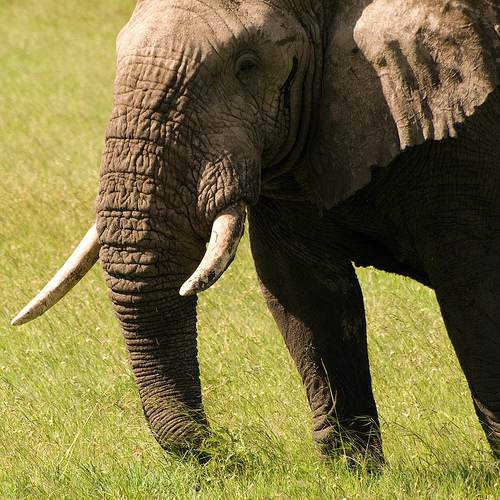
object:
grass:
[15, 462, 304, 500]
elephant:
[8, 1, 499, 478]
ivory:
[10, 223, 105, 327]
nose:
[94, 52, 215, 470]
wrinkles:
[95, 200, 168, 222]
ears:
[316, 0, 498, 205]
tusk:
[179, 201, 245, 297]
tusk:
[11, 223, 100, 327]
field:
[0, 336, 110, 499]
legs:
[253, 238, 388, 475]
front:
[77, 0, 345, 474]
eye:
[232, 49, 264, 89]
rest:
[11, 0, 500, 477]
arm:
[434, 279, 500, 465]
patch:
[227, 414, 279, 491]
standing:
[7, 0, 500, 483]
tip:
[12, 304, 38, 327]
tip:
[179, 275, 205, 298]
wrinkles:
[234, 85, 272, 119]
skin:
[124, 124, 169, 236]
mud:
[269, 17, 303, 62]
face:
[97, 0, 322, 211]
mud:
[222, 217, 242, 255]